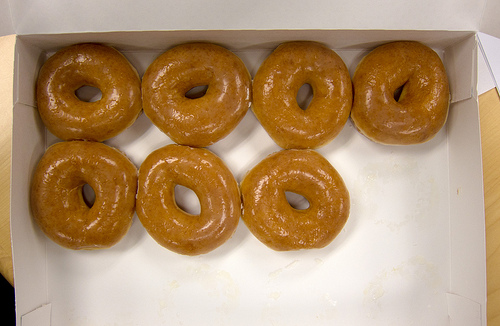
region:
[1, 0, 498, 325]
White box of doughnuts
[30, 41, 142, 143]
Glazed doughnut in box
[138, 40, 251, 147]
Glazed doughnut in box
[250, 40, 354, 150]
Glazed doughnut in box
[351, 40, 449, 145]
Glazed doughnut in box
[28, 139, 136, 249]
Glazed doughnut in box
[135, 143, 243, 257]
Glazed doughnut in box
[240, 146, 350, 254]
Glazed doughnut in box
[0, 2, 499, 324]
Box of doughnuts on table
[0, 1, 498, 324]
Open box filled with doughnuts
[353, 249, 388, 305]
prt of a base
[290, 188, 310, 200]
edge of a line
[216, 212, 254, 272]
edge of a line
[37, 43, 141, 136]
the donut is round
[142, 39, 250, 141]
the donut is brown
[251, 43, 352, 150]
the donut is glazed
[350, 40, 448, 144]
the donut is shiny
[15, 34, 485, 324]
donuts in a box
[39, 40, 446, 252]
a group of seven donuts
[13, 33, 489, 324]
the box is white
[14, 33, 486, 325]
the box is square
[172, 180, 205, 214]
hole in the donut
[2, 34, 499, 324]
the table is light colored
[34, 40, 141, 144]
glazed donut next to glazed donut in box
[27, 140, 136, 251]
glazed donut next to glazed donut in box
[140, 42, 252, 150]
glazed donut next to glazed donut in box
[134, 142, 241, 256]
glazed donut next to glazed donut in box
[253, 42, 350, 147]
glazed donut next to glazed donut in box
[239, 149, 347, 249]
glazed donut next to glazed donut in box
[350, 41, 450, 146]
glazed donut next to glazed donut in box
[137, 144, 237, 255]
glazed donut in box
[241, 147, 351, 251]
glazed donut in box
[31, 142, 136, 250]
glazed donut in box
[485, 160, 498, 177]
this is a table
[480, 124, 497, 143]
the table is brown in color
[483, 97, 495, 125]
the table is wooden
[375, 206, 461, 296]
this is a box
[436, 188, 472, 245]
the box is white in color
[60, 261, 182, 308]
the box is open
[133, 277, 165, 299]
the box is clean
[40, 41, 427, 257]
these are several doughnuts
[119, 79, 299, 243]
the doughnuts are oily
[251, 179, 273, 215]
the doughnut is brown in color